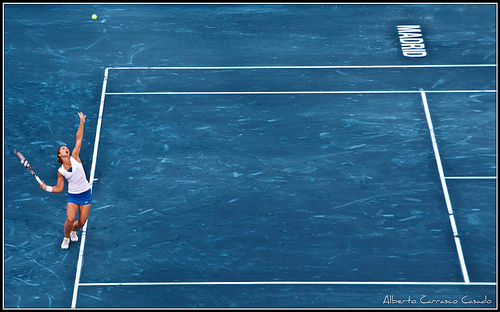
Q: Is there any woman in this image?
A: Yes, there is a woman.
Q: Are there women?
A: Yes, there is a woman.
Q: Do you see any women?
A: Yes, there is a woman.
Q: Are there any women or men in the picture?
A: Yes, there is a woman.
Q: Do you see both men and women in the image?
A: No, there is a woman but no men.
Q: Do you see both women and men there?
A: No, there is a woman but no men.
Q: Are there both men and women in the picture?
A: No, there is a woman but no men.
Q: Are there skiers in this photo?
A: No, there are no skiers.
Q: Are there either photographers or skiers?
A: No, there are no skiers or photographers.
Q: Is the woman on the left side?
A: Yes, the woman is on the left of the image.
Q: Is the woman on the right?
A: No, the woman is on the left of the image.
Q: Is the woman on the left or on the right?
A: The woman is on the left of the image.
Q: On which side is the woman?
A: The woman is on the left of the image.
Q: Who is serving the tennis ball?
A: The woman is serving the tennis ball.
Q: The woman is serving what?
A: The woman is serving a tennis ball.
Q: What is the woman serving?
A: The woman is serving a tennis ball.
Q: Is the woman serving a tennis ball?
A: Yes, the woman is serving a tennis ball.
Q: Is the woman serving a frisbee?
A: No, the woman is serving a tennis ball.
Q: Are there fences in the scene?
A: No, there are no fences.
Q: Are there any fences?
A: No, there are no fences.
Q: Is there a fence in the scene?
A: No, there are no fences.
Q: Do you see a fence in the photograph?
A: No, there are no fences.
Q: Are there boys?
A: No, there are no boys.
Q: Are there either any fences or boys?
A: No, there are no boys or fences.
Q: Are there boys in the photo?
A: No, there are no boys.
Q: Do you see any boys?
A: No, there are no boys.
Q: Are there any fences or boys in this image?
A: No, there are no boys or fences.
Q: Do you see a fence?
A: No, there are no fences.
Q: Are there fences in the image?
A: No, there are no fences.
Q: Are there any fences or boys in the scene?
A: No, there are no fences or boys.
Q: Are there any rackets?
A: Yes, there is a racket.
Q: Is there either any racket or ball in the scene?
A: Yes, there is a racket.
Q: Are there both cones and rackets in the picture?
A: No, there is a racket but no cones.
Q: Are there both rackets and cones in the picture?
A: No, there is a racket but no cones.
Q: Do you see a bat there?
A: No, there are no bats.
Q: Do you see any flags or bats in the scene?
A: No, there are no bats or flags.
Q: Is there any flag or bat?
A: No, there are no bats or flags.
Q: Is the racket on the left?
A: Yes, the racket is on the left of the image.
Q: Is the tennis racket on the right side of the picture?
A: No, the tennis racket is on the left of the image.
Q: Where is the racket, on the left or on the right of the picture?
A: The racket is on the left of the image.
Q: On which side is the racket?
A: The racket is on the left of the image.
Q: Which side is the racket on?
A: The racket is on the left of the image.